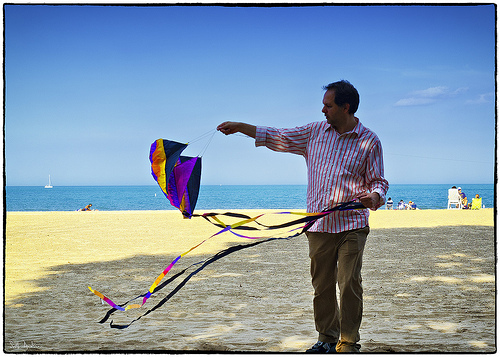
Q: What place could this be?
A: It is a beach.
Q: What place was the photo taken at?
A: It was taken at the beach.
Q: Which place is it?
A: It is a beach.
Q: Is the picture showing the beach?
A: Yes, it is showing the beach.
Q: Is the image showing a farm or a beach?
A: It is showing a beach.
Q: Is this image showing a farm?
A: No, the picture is showing a beach.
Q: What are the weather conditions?
A: It is clear.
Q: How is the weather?
A: It is clear.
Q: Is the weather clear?
A: Yes, it is clear.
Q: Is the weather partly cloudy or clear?
A: It is clear.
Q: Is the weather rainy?
A: No, it is clear.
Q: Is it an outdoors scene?
A: Yes, it is outdoors.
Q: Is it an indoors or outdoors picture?
A: It is outdoors.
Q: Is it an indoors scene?
A: No, it is outdoors.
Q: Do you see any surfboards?
A: No, there are no surfboards.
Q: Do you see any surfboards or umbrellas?
A: No, there are no surfboards or umbrellas.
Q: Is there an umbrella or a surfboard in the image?
A: No, there are no surfboards or umbrellas.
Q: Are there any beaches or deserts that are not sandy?
A: No, there is a beach but it is sandy.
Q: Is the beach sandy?
A: Yes, the beach is sandy.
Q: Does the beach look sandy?
A: Yes, the beach is sandy.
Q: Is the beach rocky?
A: No, the beach is sandy.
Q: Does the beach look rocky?
A: No, the beach is sandy.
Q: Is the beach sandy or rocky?
A: The beach is sandy.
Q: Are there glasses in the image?
A: No, there are no glasses.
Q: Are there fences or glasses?
A: No, there are no glasses or fences.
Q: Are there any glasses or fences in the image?
A: No, there are no glasses or fences.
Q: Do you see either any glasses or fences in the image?
A: No, there are no glasses or fences.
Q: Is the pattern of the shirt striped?
A: Yes, the shirt is striped.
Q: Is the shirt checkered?
A: No, the shirt is striped.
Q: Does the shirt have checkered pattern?
A: No, the shirt is striped.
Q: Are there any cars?
A: No, there are no cars.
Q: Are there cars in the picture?
A: No, there are no cars.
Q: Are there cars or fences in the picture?
A: No, there are no cars or fences.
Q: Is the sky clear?
A: Yes, the sky is clear.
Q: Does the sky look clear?
A: Yes, the sky is clear.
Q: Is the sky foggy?
A: No, the sky is clear.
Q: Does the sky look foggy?
A: No, the sky is clear.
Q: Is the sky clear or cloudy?
A: The sky is clear.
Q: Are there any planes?
A: No, there are no planes.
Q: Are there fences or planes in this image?
A: No, there are no planes or fences.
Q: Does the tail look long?
A: Yes, the tail is long.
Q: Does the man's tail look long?
A: Yes, the tail is long.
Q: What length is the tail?
A: The tail is long.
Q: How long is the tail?
A: The tail is long.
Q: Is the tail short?
A: No, the tail is long.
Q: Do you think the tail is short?
A: No, the tail is long.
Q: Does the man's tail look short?
A: No, the tail is long.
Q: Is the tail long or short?
A: The tail is long.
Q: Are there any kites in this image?
A: Yes, there is a kite.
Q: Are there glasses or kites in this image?
A: Yes, there is a kite.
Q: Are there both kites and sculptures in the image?
A: No, there is a kite but no sculptures.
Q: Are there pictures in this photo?
A: No, there are no pictures.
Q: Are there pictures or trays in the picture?
A: No, there are no pictures or trays.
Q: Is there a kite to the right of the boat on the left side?
A: Yes, there is a kite to the right of the boat.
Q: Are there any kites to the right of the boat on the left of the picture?
A: Yes, there is a kite to the right of the boat.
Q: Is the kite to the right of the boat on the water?
A: Yes, the kite is to the right of the boat.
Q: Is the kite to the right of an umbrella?
A: No, the kite is to the right of the boat.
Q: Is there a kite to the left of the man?
A: Yes, there is a kite to the left of the man.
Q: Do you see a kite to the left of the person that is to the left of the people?
A: Yes, there is a kite to the left of the man.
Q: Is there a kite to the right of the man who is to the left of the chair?
A: No, the kite is to the left of the man.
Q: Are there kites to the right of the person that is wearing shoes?
A: No, the kite is to the left of the man.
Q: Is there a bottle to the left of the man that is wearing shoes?
A: No, there is a kite to the left of the man.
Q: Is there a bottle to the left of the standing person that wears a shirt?
A: No, there is a kite to the left of the man.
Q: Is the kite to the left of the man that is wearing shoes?
A: Yes, the kite is to the left of the man.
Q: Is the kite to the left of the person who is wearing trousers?
A: Yes, the kite is to the left of the man.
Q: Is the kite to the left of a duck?
A: No, the kite is to the left of the man.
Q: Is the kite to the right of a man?
A: No, the kite is to the left of a man.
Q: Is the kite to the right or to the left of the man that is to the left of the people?
A: The kite is to the left of the man.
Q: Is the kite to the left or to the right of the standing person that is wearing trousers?
A: The kite is to the left of the man.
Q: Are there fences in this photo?
A: No, there are no fences.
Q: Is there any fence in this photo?
A: No, there are no fences.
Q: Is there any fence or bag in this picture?
A: No, there are no fences or bags.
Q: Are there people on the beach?
A: Yes, there is a person on the beach.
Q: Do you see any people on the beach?
A: Yes, there is a person on the beach.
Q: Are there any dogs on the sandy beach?
A: No, there is a person on the beach.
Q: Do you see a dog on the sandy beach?
A: No, there is a person on the beach.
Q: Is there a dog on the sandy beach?
A: No, there is a person on the beach.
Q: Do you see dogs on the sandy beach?
A: No, there is a person on the beach.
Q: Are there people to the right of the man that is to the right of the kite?
A: Yes, there is a person to the right of the man.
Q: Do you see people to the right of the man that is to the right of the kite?
A: Yes, there is a person to the right of the man.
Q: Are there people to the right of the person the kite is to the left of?
A: Yes, there is a person to the right of the man.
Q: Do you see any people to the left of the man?
A: No, the person is to the right of the man.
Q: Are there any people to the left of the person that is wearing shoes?
A: No, the person is to the right of the man.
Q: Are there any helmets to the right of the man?
A: No, there is a person to the right of the man.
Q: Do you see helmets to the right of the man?
A: No, there is a person to the right of the man.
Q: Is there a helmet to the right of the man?
A: No, there is a person to the right of the man.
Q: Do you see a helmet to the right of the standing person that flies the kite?
A: No, there is a person to the right of the man.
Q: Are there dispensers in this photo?
A: No, there are no dispensers.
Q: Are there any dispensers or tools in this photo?
A: No, there are no dispensers or tools.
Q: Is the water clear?
A: Yes, the water is clear.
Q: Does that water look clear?
A: Yes, the water is clear.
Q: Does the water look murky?
A: No, the water is clear.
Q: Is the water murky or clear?
A: The water is clear.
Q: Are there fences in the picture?
A: No, there are no fences.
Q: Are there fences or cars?
A: No, there are no fences or cars.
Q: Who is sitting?
A: The people are sitting.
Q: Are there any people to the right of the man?
A: Yes, there are people to the right of the man.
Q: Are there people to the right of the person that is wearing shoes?
A: Yes, there are people to the right of the man.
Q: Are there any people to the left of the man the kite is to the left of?
A: No, the people are to the right of the man.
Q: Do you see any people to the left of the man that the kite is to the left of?
A: No, the people are to the right of the man.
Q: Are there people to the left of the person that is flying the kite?
A: No, the people are to the right of the man.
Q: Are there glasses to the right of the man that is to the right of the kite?
A: No, there are people to the right of the man.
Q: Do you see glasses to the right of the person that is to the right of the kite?
A: No, there are people to the right of the man.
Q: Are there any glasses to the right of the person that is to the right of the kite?
A: No, there are people to the right of the man.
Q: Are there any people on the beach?
A: Yes, there are people on the beach.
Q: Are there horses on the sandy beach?
A: No, there are people on the beach.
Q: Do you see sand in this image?
A: Yes, there is sand.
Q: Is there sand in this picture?
A: Yes, there is sand.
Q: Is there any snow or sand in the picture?
A: Yes, there is sand.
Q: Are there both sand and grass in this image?
A: No, there is sand but no grass.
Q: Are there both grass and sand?
A: No, there is sand but no grass.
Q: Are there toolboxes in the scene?
A: No, there are no toolboxes.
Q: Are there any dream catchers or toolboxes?
A: No, there are no toolboxes or dream catchers.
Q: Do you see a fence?
A: No, there are no fences.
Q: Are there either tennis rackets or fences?
A: No, there are no fences or tennis rackets.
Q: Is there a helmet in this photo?
A: No, there are no helmets.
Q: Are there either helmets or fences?
A: No, there are no helmets or fences.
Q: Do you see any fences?
A: No, there are no fences.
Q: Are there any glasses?
A: No, there are no glasses.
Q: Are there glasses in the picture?
A: No, there are no glasses.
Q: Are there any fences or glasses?
A: No, there are no glasses or fences.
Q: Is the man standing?
A: Yes, the man is standing.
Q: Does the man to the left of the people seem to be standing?
A: Yes, the man is standing.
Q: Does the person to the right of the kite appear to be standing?
A: Yes, the man is standing.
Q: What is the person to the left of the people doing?
A: The man is standing.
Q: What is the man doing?
A: The man is standing.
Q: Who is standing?
A: The man is standing.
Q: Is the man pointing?
A: No, the man is standing.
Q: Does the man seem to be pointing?
A: No, the man is standing.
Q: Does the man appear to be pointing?
A: No, the man is standing.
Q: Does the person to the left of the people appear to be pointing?
A: No, the man is standing.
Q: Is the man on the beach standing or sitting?
A: The man is standing.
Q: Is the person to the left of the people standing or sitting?
A: The man is standing.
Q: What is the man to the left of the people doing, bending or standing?
A: The man is standing.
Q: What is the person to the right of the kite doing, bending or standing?
A: The man is standing.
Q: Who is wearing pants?
A: The man is wearing pants.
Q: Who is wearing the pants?
A: The man is wearing pants.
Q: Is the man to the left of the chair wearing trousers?
A: Yes, the man is wearing trousers.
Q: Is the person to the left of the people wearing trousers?
A: Yes, the man is wearing trousers.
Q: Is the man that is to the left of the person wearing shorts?
A: No, the man is wearing trousers.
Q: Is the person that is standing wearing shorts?
A: No, the man is wearing trousers.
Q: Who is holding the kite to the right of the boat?
A: The man is holding the kite.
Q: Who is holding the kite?
A: The man is holding the kite.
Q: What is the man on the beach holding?
A: The man is holding the kite.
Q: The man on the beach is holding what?
A: The man is holding the kite.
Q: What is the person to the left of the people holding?
A: The man is holding the kite.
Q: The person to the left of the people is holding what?
A: The man is holding the kite.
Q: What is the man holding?
A: The man is holding the kite.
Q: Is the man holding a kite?
A: Yes, the man is holding a kite.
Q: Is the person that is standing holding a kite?
A: Yes, the man is holding a kite.